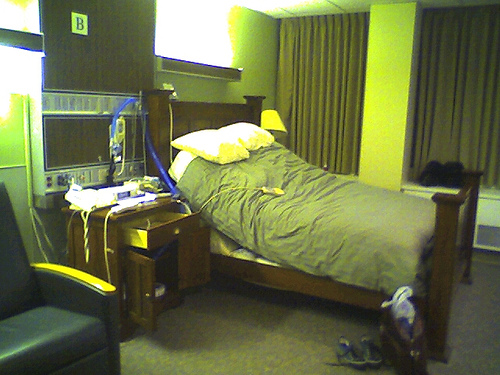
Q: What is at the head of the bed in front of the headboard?
A: The pillows.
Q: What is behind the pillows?
A: The headboard.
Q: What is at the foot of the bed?
A: The footboard.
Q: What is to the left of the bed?
A: A wooden night stand.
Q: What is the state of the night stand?
A: Disorganized.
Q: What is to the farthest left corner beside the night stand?
A: An arm chair.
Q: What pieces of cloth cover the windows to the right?
A: The curtains.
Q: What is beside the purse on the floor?
A: A pair of shoes.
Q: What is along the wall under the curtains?
A: The air conditioner.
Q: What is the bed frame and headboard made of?
A: Wood.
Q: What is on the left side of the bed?
A: Wooden night stand.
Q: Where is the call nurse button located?
A: On the bed.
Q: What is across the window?
A: Brown curtain.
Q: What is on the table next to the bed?
A: Medical devices and tubing.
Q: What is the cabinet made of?
A: Wood.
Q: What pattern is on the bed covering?
A: Stripes.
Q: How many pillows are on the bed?
A: Two.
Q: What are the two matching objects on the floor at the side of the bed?
A: Shoes.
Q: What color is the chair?
A: Black.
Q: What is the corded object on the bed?
A: Bed control.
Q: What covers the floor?
A: Carpet.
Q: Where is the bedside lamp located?
A: Beside the bed.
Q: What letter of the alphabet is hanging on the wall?
A: B.